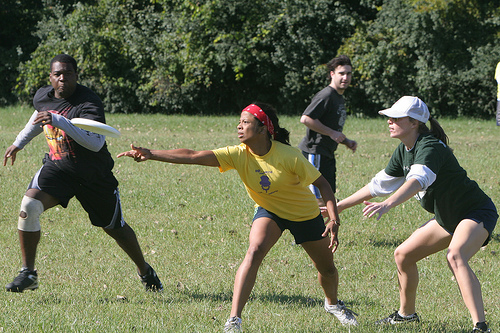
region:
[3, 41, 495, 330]
they are in a park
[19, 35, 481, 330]
they are playing Ultimate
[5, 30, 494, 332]
they are playing Ultimate Frisbee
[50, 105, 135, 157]
the flying disc is white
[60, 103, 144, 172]
this is a white frisbee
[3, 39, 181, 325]
he is running on the grass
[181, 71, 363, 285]
she is wearing a yellow tee shirt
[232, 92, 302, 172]
she has a red bandana in her hair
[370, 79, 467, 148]
she is wearing a white baseball cap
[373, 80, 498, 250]
she is wearing a green tee shirt over a white sweater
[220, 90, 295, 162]
the head of a woman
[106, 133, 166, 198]
the hand of a woman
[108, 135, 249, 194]
the arm of a woman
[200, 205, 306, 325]
the leg of a woman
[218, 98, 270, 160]
the eyes of a woman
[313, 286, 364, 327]
the foot of a woman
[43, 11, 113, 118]
the head of a man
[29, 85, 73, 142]
the hand of a man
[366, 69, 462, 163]
a woman wearing a hat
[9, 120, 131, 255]
a man wearing shorts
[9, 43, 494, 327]
four people standing in a field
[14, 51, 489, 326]
four people playing frisbee in a park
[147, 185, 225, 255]
green grass of the field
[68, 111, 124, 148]
a white frisbee in midair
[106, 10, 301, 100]
trees growing on the edge of the field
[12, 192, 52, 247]
white brace on the man's knee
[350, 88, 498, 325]
a woman wearing a green shirt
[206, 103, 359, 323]
a woman wearing a yellow shirt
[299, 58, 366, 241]
a man wearing a dark grey shirt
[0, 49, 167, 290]
a man wearing a black shirt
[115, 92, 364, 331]
person wearing yellow shirt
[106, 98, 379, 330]
person wearing a red head band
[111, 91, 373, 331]
person wearing a pair of shoe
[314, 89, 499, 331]
person wearing a white hat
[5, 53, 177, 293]
person wearing a black short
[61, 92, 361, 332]
person catching a Frisbee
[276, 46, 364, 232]
person wearing a black shirt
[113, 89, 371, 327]
woman wearing a short pant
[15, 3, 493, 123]
trees and bushes on ground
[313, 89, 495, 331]
woman wearing green shirt